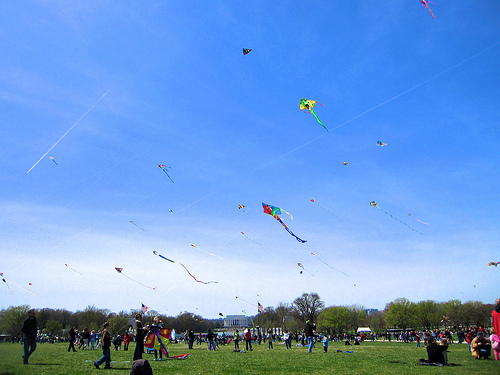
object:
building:
[223, 315, 251, 327]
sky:
[349, 13, 477, 101]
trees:
[249, 290, 495, 338]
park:
[0, 292, 499, 374]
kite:
[168, 209, 173, 213]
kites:
[168, 209, 173, 213]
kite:
[238, 204, 254, 216]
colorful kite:
[262, 202, 308, 244]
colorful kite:
[298, 97, 330, 134]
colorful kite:
[157, 163, 174, 183]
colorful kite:
[113, 266, 155, 289]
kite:
[113, 265, 156, 290]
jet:
[25, 92, 105, 175]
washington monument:
[223, 314, 253, 327]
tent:
[357, 326, 372, 333]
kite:
[243, 47, 252, 55]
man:
[21, 308, 37, 365]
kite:
[310, 199, 337, 218]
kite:
[189, 243, 225, 261]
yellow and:
[311, 101, 316, 108]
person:
[470, 331, 493, 359]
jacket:
[470, 336, 491, 358]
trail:
[175, 42, 496, 215]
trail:
[27, 90, 110, 172]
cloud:
[53, 233, 174, 305]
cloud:
[228, 239, 439, 301]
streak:
[20, 77, 117, 178]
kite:
[49, 156, 59, 165]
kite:
[0, 272, 36, 296]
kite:
[295, 96, 330, 133]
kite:
[375, 140, 387, 147]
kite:
[488, 261, 500, 267]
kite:
[343, 161, 348, 165]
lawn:
[249, 357, 344, 364]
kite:
[369, 200, 424, 237]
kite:
[310, 252, 348, 276]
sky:
[419, 101, 496, 240]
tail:
[274, 215, 307, 244]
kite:
[240, 231, 263, 246]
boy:
[93, 322, 113, 370]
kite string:
[218, 313, 223, 317]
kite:
[152, 250, 218, 285]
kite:
[375, 140, 387, 148]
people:
[0, 310, 492, 370]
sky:
[3, 4, 132, 125]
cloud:
[335, 183, 360, 193]